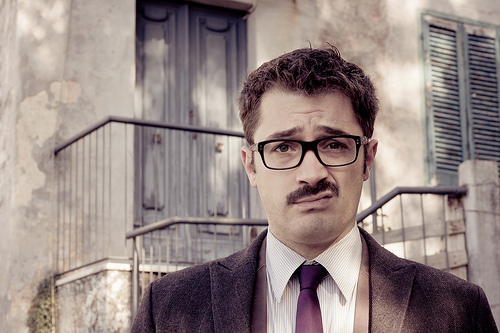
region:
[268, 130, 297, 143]
edge of a speck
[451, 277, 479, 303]
part of a shoulder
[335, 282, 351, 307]
edge of a collar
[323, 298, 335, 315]
part of a shirt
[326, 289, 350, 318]
part of a shade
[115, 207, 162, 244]
part of a metal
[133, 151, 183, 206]
part of a balcony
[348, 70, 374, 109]
part of some hair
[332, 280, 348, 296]
edge of a collar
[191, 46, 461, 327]
man in suit and coat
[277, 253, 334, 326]
purple tie in collar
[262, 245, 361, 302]
collar of dress shirt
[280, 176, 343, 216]
mustache on man's face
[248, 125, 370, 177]
glasses with black rim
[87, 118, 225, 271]
railing in front of door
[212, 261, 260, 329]
lapel of coat over jacket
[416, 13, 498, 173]
closed shutters on building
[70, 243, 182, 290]
platform in front of door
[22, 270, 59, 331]
vegetation on building wall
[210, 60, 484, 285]
Man sneering at camera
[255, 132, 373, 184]
Man wearing dark glasses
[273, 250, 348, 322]
He is wearing a purple tie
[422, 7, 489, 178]
wooden shutters on window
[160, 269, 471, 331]
Purple suit jacket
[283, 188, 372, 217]
Mustache over lip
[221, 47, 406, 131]
Man has dark colored hair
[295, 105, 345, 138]
Crease on forehead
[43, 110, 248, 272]
Fence surrounding door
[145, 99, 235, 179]
Door handles on door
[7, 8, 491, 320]
This man did not want his picture taken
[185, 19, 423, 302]
he has a negative look on his face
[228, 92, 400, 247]
he is wearing glasses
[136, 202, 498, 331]
he is dressed nicely in a puple tie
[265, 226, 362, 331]
he is wearing a puple tie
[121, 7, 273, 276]
a gray door behind the man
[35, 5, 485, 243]
the building is old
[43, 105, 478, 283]
there is a rail behind the man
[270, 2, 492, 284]
a stone wall in the background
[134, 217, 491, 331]
the man's coat is smoky grey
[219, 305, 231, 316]
man wearing black suit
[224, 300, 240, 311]
man wearing black suit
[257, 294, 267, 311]
man wearing black suit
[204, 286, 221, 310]
man wearing black suit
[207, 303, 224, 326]
man wearing black suit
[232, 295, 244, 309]
man wearing black suit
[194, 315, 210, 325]
man wearing black suit